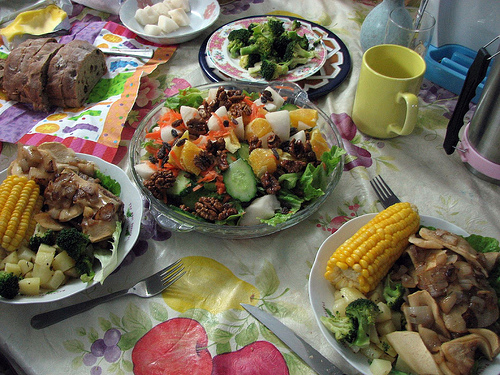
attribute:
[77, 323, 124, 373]
grapes — purple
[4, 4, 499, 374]
cloth — table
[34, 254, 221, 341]
fork — silver